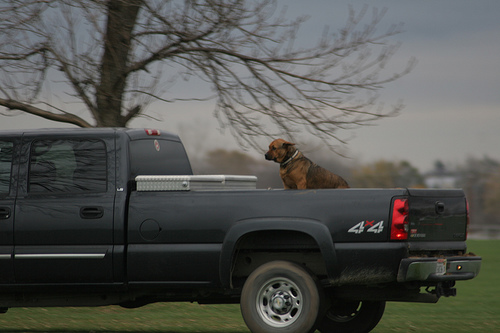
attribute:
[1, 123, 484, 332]
truck — black, grey, dirty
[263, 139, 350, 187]
dog — brown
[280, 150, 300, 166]
collar — white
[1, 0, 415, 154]
tree — bare, large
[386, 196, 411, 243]
light — red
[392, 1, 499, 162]
sky — grey, cloudy, blue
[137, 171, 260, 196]
box — silver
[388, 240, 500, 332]
grass — green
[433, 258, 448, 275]
plate — white